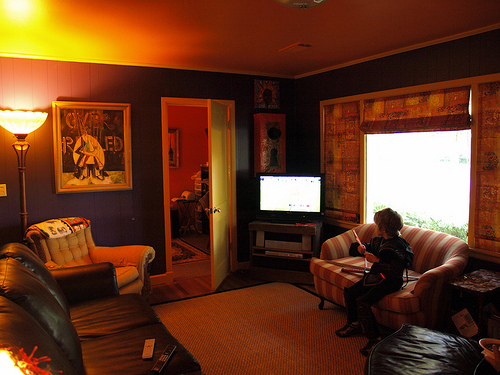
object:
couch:
[309, 223, 471, 331]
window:
[361, 128, 472, 246]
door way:
[159, 95, 234, 291]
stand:
[248, 220, 323, 262]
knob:
[204, 207, 221, 214]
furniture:
[21, 217, 155, 294]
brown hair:
[0, 242, 203, 372]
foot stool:
[365, 323, 491, 375]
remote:
[150, 344, 178, 374]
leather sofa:
[0, 236, 202, 373]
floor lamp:
[0, 107, 48, 243]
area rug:
[149, 279, 381, 374]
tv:
[258, 170, 323, 218]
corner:
[215, 61, 330, 299]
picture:
[50, 100, 132, 194]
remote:
[142, 339, 156, 359]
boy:
[335, 208, 413, 355]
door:
[208, 98, 235, 292]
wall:
[48, 192, 169, 230]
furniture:
[10, 262, 141, 366]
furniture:
[400, 236, 450, 300]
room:
[0, 0, 499, 374]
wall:
[320, 109, 368, 226]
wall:
[2, 152, 23, 243]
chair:
[308, 223, 470, 331]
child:
[334, 208, 417, 356]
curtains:
[318, 74, 499, 255]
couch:
[0, 242, 206, 374]